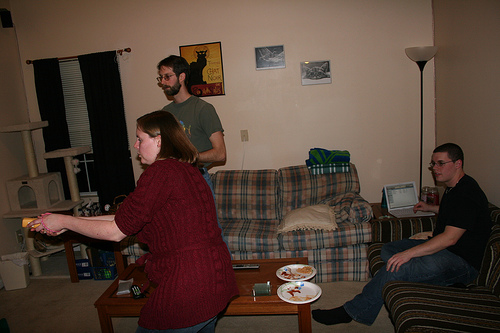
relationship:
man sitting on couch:
[362, 138, 492, 288] [365, 198, 498, 330]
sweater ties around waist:
[115, 156, 243, 323] [148, 237, 225, 260]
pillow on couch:
[276, 202, 339, 242] [216, 159, 371, 267]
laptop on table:
[381, 178, 433, 221] [372, 206, 388, 217]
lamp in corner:
[402, 40, 441, 178] [406, 3, 448, 144]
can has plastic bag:
[0, 249, 31, 295] [1, 248, 30, 267]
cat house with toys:
[3, 120, 82, 217] [71, 193, 103, 217]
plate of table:
[272, 255, 326, 310] [91, 252, 316, 332]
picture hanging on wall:
[176, 39, 229, 99] [172, 9, 350, 137]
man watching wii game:
[362, 138, 492, 288] [13, 207, 64, 242]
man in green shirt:
[153, 49, 220, 137] [162, 95, 225, 148]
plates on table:
[272, 255, 326, 310] [91, 252, 316, 332]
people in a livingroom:
[22, 51, 498, 332] [4, 2, 497, 332]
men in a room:
[157, 51, 492, 212] [4, 2, 497, 332]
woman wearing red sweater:
[33, 105, 240, 330] [115, 156, 243, 323]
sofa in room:
[216, 159, 371, 267] [4, 2, 497, 332]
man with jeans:
[362, 138, 492, 288] [338, 238, 480, 321]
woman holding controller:
[33, 105, 240, 330] [20, 214, 45, 231]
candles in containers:
[417, 181, 440, 205] [423, 189, 439, 204]